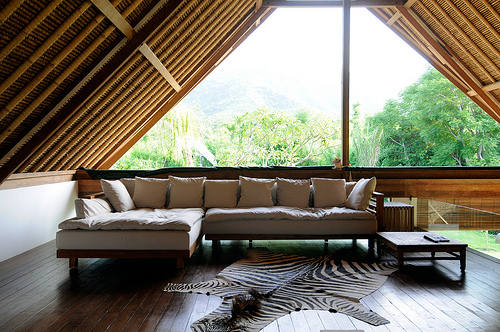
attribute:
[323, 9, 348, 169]
beam — wooden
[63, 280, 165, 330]
floor — part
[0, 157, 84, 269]
walls — short, white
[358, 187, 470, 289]
table — long, dark wood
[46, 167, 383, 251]
couch — wooden handle 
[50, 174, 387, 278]
couch — white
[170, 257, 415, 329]
carpet — part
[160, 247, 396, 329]
carpet — part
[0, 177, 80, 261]
wall — white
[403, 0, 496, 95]
ceiling — thatched, vaulted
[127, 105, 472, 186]
foliage — lush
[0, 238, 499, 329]
floor — dark, hardwood, brown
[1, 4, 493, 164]
roof — wooden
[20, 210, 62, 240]
white wall — short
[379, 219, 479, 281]
table — small end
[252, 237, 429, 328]
carpet — part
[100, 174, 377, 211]
cushions — white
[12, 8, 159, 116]
roof — slanted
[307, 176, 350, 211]
pillow — white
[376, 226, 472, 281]
table — wooden, small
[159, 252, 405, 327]
rug — Zebra print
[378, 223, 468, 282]
table — wooden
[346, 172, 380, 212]
pillow — tan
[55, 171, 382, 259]
sofa — white, leather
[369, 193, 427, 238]
table — side, short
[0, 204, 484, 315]
floor — wooden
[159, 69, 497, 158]
trees — large , green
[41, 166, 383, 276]
sofa — large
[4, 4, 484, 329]
room — living 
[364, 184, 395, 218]
handle — wooden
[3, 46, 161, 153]
roof — thatched 